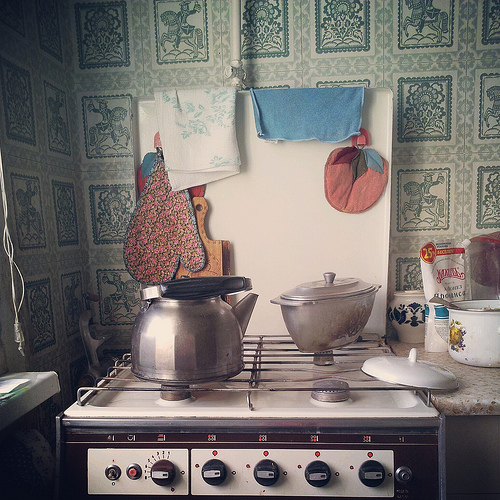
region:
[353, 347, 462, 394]
White metal top to pot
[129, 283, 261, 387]
Grey metal tea pot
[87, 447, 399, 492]
Black stove top controls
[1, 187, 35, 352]
Plastic control to drapes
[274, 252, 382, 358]
Distorted glassware sitting on stove top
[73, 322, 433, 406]
Metal grillwork and burners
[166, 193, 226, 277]
Brown wooden cutting board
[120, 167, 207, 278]
Hand shaped pot holder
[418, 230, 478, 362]
Ingredients sitting on counter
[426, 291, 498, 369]
Open pot with utensil sticking out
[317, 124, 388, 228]
circular pot holder hanging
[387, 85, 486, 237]
decorative tile on the wall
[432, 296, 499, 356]
utensil sticking out of a pot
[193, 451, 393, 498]
black knobs on an oven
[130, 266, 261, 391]
shiny silver tea kettle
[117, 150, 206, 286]
oven mitt hanging up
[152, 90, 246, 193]
tea towel folded and hanging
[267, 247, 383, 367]
silver container with a lid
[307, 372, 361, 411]
silver stove burner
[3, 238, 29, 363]
white pull for blinds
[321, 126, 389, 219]
pumpkin-designed pot holder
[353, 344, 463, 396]
white pot top between counter and stove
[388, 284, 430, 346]
white tin with blue pattern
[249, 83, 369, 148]
blue towel on white board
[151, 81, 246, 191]
white towel with green leaves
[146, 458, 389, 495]
oven knobs turned horizontally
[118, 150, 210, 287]
red pot holder with blue edges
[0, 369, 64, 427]
partial view of white window sill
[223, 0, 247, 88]
white pipe behind white board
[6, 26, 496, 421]
white wallpaper with green pattern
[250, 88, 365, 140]
blue wash cloth draped over wall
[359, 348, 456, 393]
white metal lid on the stove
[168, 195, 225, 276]
section of wooden cutting board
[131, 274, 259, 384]
silver tea pot with black handle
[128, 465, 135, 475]
small red button on the front of the stove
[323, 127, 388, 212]
pink pot holder with designs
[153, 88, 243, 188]
white paper towel with blue designs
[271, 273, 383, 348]
silver metal dish with lid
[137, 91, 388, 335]
square white panel on the wall behind the stove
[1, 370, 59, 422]
section of kitchen sink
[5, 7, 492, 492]
An oven in a kitchen.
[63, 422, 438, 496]
Controls on an oven.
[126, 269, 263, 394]
Tea kettle on a stove top.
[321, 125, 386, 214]
Potholder on a wall.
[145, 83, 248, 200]
White and blue towel hanging on a wall.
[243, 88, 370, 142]
Blue towel hanging on a wall.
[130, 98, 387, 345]
White board behind an oven.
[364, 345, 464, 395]
Lid sitting on a stove top.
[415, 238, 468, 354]
White bag on a counter top.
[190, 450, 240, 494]
One black knob of an oven.